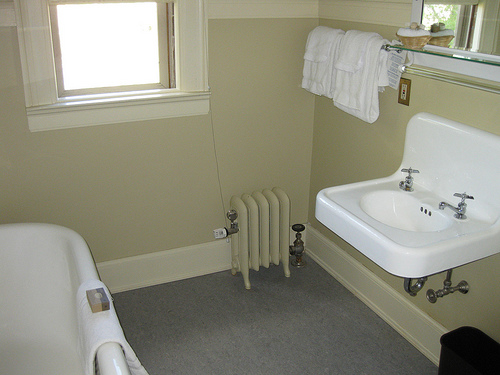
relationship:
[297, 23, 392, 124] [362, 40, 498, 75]
towel on rack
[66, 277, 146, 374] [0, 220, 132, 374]
mat hanging from tub